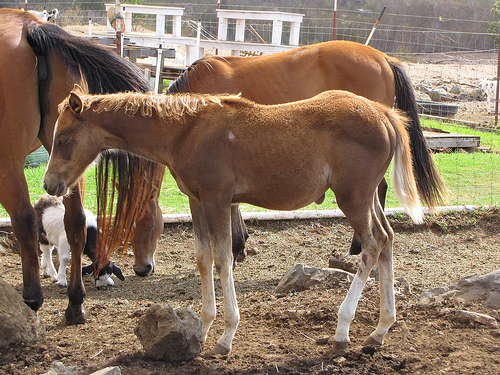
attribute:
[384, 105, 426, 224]
tail — brown, white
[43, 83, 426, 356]
horse — small, brown, squinting, young, light tan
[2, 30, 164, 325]
horse — adult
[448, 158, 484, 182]
grass — green, small patch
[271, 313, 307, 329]
brown dirt — small patch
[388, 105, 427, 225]
tail — brown, white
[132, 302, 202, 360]
rock — medium-sized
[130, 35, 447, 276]
horse — young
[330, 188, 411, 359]
legs — long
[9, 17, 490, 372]
horses — several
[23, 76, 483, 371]
horse — brown, young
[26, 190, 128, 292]
goat — young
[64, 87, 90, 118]
ear — to left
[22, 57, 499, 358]
horse — in back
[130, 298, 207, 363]
rock — gray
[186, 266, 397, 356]
bottom legs — white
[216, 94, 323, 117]
back — brown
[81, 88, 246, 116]
hair — gold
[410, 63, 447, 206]
tail — black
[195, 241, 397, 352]
legs — white